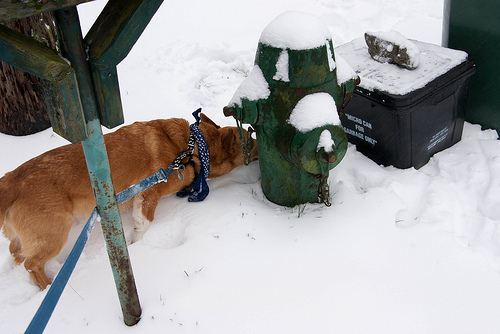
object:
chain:
[313, 155, 336, 210]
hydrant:
[212, 11, 371, 210]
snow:
[255, 8, 341, 45]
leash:
[23, 166, 175, 334]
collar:
[184, 116, 212, 206]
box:
[331, 26, 482, 174]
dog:
[3, 97, 271, 293]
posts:
[46, 0, 150, 328]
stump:
[1, 10, 77, 139]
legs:
[23, 235, 62, 295]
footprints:
[387, 207, 422, 231]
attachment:
[287, 114, 350, 180]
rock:
[355, 28, 419, 70]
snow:
[11, 169, 498, 334]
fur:
[38, 163, 79, 212]